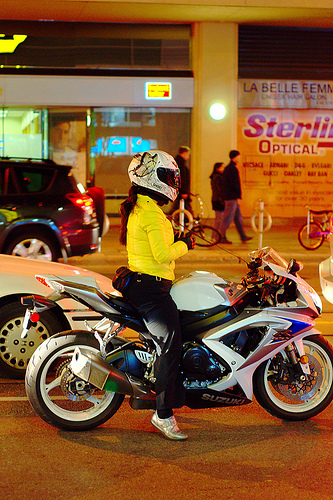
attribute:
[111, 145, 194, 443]
woman — sexy, young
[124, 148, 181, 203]
helmet — white, beautiful, designed, artsy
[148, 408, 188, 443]
shoe — silver, casual, nice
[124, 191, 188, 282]
jacket — yellow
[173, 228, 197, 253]
gloves — black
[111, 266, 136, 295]
fanny pack — black, leather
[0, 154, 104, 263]
suv — dark blue, grey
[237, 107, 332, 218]
advertisement — yellow, large, red, sign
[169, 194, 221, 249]
bicycle — parked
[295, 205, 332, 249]
bicycle — parked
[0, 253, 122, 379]
car — white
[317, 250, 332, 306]
car — white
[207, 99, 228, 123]
light — circular, on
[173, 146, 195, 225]
man — young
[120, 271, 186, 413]
pants — black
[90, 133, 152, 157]
lights — blue, reflection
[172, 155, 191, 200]
jacket — black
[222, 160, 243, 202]
jacket — black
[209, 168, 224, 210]
jacket — black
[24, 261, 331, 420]
motorcycle — brand new, white